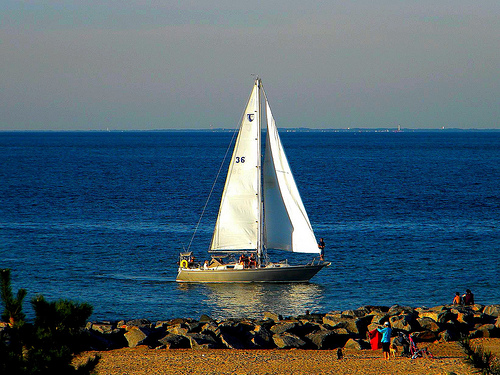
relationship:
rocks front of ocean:
[129, 317, 350, 355] [0, 129, 500, 324]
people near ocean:
[447, 284, 490, 312] [0, 129, 500, 324]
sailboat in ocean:
[178, 71, 333, 283] [0, 129, 500, 324]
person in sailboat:
[315, 234, 331, 267] [178, 71, 333, 283]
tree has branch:
[6, 266, 89, 374] [13, 284, 30, 311]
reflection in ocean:
[13, 214, 206, 239] [0, 129, 500, 324]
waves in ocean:
[30, 233, 178, 295] [0, 129, 500, 324]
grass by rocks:
[59, 342, 283, 358] [129, 317, 350, 355]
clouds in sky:
[110, 13, 326, 76] [17, 14, 482, 118]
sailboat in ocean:
[235, 71, 322, 289] [0, 129, 500, 324]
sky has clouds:
[17, 14, 482, 118] [110, 13, 326, 76]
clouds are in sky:
[110, 13, 326, 76] [17, 14, 482, 118]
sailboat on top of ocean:
[235, 71, 322, 289] [0, 129, 500, 324]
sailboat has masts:
[235, 71, 322, 289] [211, 101, 322, 252]